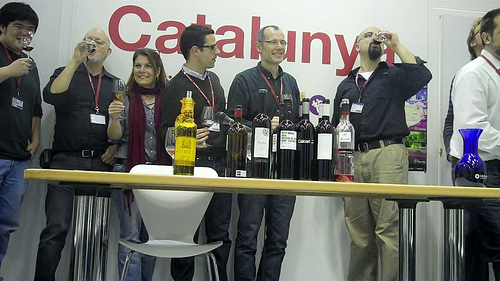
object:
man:
[226, 25, 300, 281]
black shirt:
[43, 64, 122, 153]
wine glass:
[20, 30, 37, 70]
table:
[22, 168, 499, 280]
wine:
[276, 93, 299, 180]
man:
[329, 26, 432, 281]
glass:
[370, 30, 388, 44]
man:
[32, 27, 124, 281]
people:
[0, 2, 500, 281]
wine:
[333, 98, 356, 175]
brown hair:
[124, 47, 168, 97]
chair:
[116, 164, 223, 281]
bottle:
[173, 91, 198, 176]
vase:
[454, 128, 489, 188]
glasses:
[80, 37, 110, 49]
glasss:
[225, 104, 248, 178]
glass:
[270, 38, 287, 46]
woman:
[107, 47, 171, 280]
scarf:
[122, 85, 167, 217]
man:
[157, 23, 233, 281]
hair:
[180, 24, 215, 60]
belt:
[55, 149, 105, 158]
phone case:
[39, 149, 53, 169]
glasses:
[189, 44, 217, 51]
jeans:
[166, 149, 232, 281]